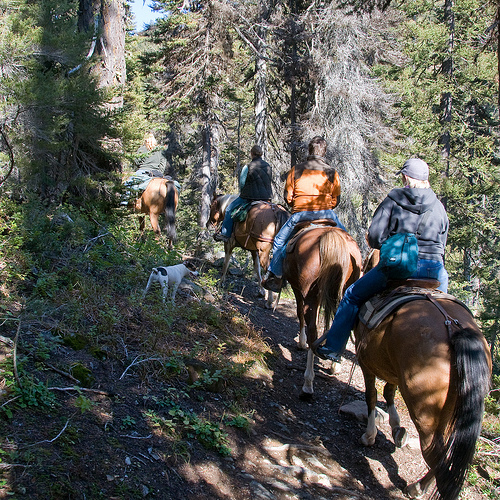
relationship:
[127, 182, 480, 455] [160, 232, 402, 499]
horses are on a path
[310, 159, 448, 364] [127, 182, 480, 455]
person are on horses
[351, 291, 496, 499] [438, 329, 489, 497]
horse has a tail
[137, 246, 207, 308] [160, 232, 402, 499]
dog on path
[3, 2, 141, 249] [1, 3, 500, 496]
trees are in woods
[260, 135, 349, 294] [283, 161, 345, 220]
person has a jacket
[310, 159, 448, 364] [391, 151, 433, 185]
person has a cap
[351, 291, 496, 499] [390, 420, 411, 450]
horse has a back hoof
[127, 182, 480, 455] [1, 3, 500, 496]
horses are in woods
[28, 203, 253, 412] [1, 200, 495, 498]
grass on ground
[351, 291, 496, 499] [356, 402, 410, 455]
horse has hooves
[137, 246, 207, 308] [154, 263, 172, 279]
dog has a spot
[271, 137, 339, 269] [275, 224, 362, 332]
person on a horse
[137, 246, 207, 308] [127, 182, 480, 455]
dog looking at horses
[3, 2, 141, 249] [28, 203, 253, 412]
trees are on side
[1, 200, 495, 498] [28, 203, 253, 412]
ground has plants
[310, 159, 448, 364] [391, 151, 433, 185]
person has a hat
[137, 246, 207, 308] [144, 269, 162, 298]
dog has a tail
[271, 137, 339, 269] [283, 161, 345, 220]
person has a jacket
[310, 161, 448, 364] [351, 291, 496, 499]
person on a horse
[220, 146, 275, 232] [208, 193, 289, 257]
person on a horse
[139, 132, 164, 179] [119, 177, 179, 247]
person on a horses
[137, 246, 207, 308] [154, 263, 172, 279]
dog has spot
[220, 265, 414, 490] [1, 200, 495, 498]
shadow on ground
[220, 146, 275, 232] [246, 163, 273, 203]
person has a vest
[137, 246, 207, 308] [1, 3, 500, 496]
dog in woods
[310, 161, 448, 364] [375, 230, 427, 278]
person has a pack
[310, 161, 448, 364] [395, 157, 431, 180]
person has a cap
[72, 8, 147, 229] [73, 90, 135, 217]
tree has a trunk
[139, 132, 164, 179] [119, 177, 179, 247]
person riding horses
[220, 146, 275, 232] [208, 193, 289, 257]
person riding horse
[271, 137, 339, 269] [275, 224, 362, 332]
person riding horse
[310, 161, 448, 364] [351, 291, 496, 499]
person riding horse